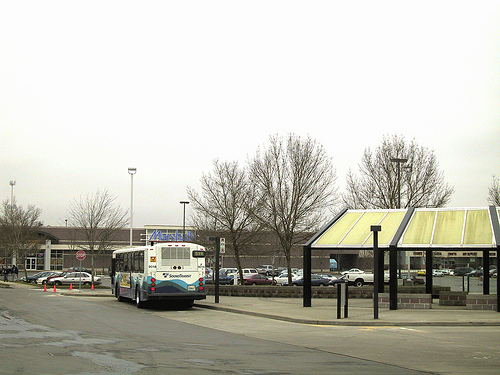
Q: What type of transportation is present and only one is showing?
A: Bus.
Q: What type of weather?
A: Cloudy.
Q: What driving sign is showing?
A: Stop sign.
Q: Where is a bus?
A: On the street.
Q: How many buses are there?
A: One.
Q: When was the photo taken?
A: Daytime.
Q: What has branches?
A: Trees.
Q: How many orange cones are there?
A: Four.